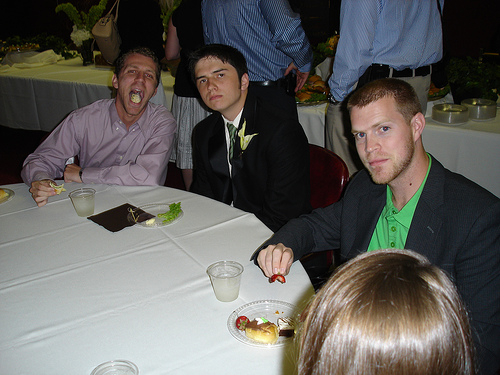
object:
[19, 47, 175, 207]
boys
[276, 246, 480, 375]
female companion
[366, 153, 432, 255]
polo shirt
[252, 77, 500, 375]
guy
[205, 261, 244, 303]
cup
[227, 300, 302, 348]
plate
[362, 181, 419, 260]
shirt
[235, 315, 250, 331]
strawberry